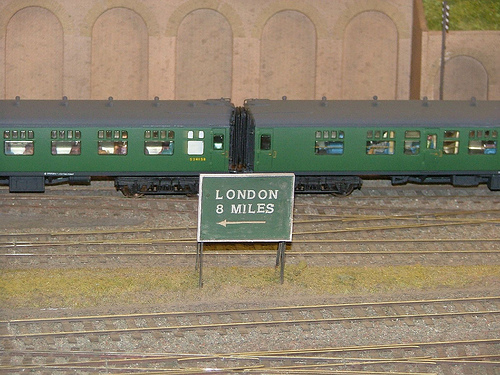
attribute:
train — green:
[0, 96, 498, 199]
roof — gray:
[246, 95, 497, 123]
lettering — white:
[214, 190, 279, 202]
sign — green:
[196, 173, 294, 242]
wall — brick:
[0, 1, 411, 102]